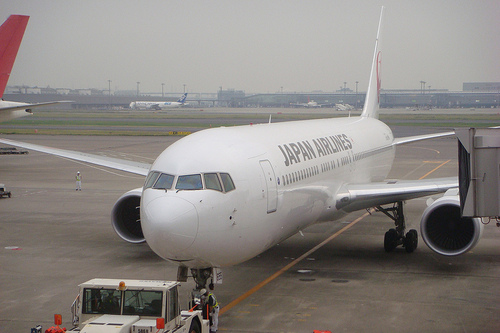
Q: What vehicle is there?
A: Airplane.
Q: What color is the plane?
A: White.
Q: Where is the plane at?
A: Airport terminal.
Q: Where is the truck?
A: Front of plane.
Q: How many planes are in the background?
A: One.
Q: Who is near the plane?
A: Man.